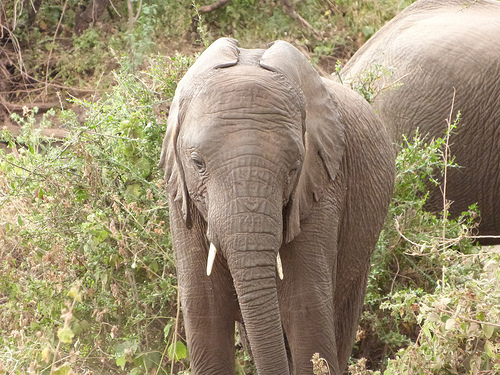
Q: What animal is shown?
A: Elephant.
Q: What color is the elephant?
A: Grey.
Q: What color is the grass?
A: Yellow.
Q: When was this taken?
A: Daytime.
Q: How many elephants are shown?
A: 2.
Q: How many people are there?
A: 0.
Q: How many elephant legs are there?
A: 3.